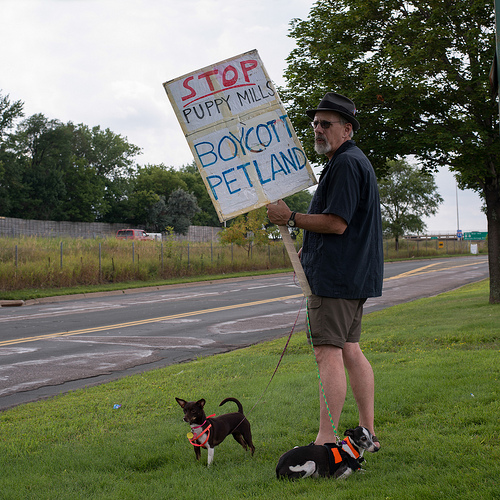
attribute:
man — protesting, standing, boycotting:
[266, 94, 382, 448]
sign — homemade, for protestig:
[162, 48, 319, 224]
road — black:
[1, 254, 496, 407]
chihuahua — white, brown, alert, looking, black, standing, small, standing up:
[175, 397, 256, 469]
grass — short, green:
[4, 276, 497, 498]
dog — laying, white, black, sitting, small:
[276, 427, 380, 486]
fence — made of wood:
[1, 218, 262, 245]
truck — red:
[117, 230, 156, 243]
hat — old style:
[305, 93, 362, 129]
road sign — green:
[466, 231, 487, 243]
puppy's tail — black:
[218, 399, 243, 413]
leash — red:
[229, 293, 310, 434]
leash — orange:
[305, 302, 343, 447]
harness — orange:
[325, 437, 363, 471]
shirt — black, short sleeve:
[300, 141, 385, 298]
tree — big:
[278, 0, 498, 306]